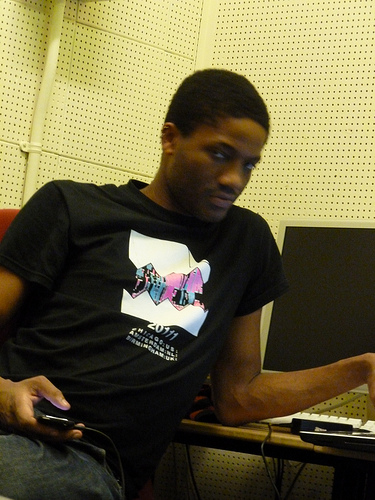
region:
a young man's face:
[158, 57, 273, 225]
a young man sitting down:
[0, 62, 284, 499]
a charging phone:
[37, 404, 82, 434]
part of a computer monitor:
[260, 207, 374, 397]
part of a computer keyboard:
[297, 407, 372, 430]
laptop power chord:
[287, 415, 356, 433]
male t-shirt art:
[114, 220, 220, 371]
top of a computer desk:
[176, 406, 369, 463]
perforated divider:
[270, 0, 368, 197]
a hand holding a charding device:
[1, 363, 118, 453]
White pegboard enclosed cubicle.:
[16, 0, 151, 162]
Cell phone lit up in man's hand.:
[22, 382, 80, 442]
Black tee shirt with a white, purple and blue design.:
[107, 224, 220, 361]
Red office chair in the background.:
[0, 198, 19, 241]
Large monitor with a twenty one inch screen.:
[258, 219, 373, 375]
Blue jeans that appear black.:
[0, 450, 126, 498]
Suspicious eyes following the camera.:
[199, 142, 270, 171]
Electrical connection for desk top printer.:
[289, 417, 355, 441]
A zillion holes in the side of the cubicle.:
[279, 22, 366, 197]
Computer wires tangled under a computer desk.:
[180, 421, 313, 498]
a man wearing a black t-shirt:
[21, 66, 291, 356]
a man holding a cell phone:
[7, 61, 274, 461]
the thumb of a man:
[31, 373, 76, 411]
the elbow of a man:
[208, 384, 252, 428]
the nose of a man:
[218, 166, 243, 191]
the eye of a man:
[206, 145, 227, 162]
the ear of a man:
[160, 122, 177, 157]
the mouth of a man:
[206, 190, 237, 210]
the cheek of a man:
[176, 160, 210, 194]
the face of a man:
[202, 122, 258, 208]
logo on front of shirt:
[113, 228, 210, 361]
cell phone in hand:
[37, 412, 71, 429]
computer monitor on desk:
[259, 217, 374, 394]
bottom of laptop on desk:
[300, 428, 373, 448]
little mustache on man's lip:
[204, 184, 242, 196]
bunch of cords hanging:
[176, 418, 310, 498]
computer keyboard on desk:
[260, 411, 374, 434]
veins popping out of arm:
[227, 380, 281, 412]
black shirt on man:
[0, 179, 290, 495]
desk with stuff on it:
[178, 420, 371, 473]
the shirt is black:
[45, 192, 261, 418]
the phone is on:
[27, 401, 106, 439]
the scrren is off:
[287, 222, 371, 372]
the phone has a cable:
[38, 407, 97, 442]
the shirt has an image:
[125, 232, 235, 368]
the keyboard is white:
[312, 410, 351, 426]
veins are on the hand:
[233, 386, 271, 415]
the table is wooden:
[239, 420, 292, 453]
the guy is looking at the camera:
[2, 122, 372, 498]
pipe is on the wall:
[13, 117, 49, 164]